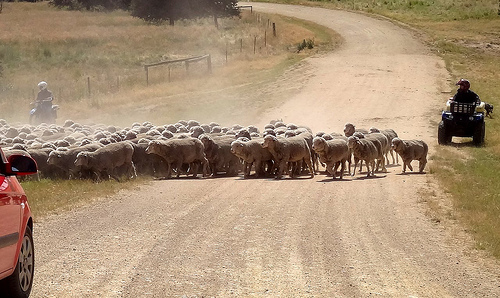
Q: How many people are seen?
A: 2.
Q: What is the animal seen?
A: Sheep.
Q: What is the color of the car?
A: Red.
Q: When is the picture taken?
A: Daytime.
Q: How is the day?
A: Sunny.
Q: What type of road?
A: Mud.